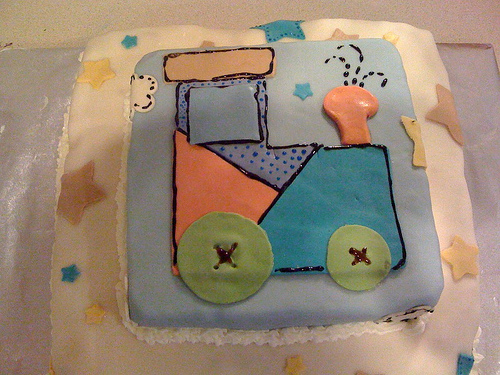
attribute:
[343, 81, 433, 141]
stack — peach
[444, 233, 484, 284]
star — light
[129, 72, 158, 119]
cloud — white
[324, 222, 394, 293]
wheel — small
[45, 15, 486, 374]
cake — square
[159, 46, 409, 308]
train — drawing 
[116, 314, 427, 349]
icing border — white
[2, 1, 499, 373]
table —  white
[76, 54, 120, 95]
star — yellow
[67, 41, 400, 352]
icing — blue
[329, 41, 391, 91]
smoke — black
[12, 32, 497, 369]
table — clean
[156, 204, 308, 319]
wheel — green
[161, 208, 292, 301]
tire — green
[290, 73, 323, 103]
star — blue